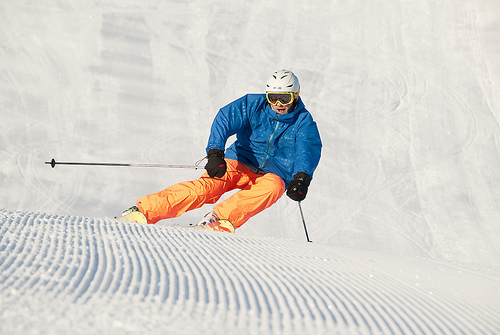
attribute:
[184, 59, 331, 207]
person — slanting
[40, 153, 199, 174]
poles — stretched out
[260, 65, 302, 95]
helmet — white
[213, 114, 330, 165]
jacket — blue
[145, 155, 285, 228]
pants — orange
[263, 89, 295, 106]
goggles — yellow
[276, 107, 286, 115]
mouth — open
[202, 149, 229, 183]
glove — black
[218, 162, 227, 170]
spot — red